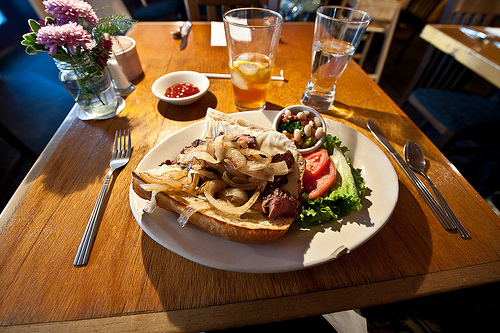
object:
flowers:
[19, 0, 137, 56]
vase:
[52, 51, 126, 121]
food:
[131, 109, 364, 244]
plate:
[129, 110, 399, 274]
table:
[2, 13, 474, 323]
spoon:
[403, 141, 471, 239]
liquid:
[231, 53, 275, 109]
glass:
[223, 8, 284, 112]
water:
[300, 5, 372, 112]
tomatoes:
[298, 148, 337, 201]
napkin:
[210, 16, 252, 47]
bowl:
[151, 70, 210, 105]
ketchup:
[165, 83, 200, 98]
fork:
[72, 129, 131, 266]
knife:
[366, 119, 472, 239]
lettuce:
[284, 134, 366, 229]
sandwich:
[132, 106, 306, 243]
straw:
[199, 70, 285, 81]